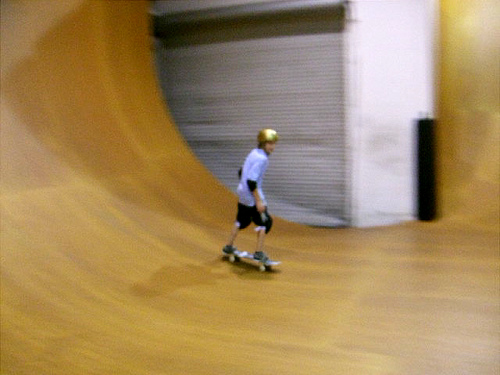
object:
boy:
[222, 129, 278, 261]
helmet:
[257, 128, 278, 154]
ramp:
[0, 0, 321, 375]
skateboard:
[222, 245, 281, 272]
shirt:
[237, 149, 270, 207]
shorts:
[233, 202, 273, 234]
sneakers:
[223, 245, 264, 259]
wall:
[159, 0, 447, 228]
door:
[417, 118, 438, 222]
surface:
[209, 185, 472, 366]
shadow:
[124, 238, 227, 306]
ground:
[0, 219, 498, 374]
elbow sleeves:
[238, 165, 257, 193]